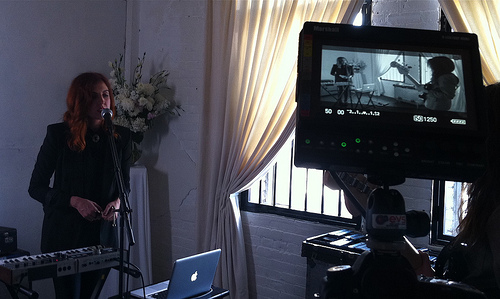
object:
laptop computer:
[131, 247, 221, 297]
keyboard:
[3, 244, 127, 279]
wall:
[130, 0, 233, 264]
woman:
[417, 58, 470, 110]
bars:
[258, 145, 282, 214]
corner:
[117, 25, 203, 174]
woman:
[24, 69, 158, 267]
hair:
[59, 92, 92, 154]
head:
[58, 67, 122, 136]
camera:
[290, 19, 492, 183]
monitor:
[287, 16, 491, 188]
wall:
[237, 204, 359, 296]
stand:
[88, 162, 133, 216]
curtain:
[194, 2, 499, 290]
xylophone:
[333, 205, 424, 287]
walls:
[2, 14, 49, 86]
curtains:
[454, 0, 496, 72]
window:
[238, 0, 498, 243]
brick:
[132, 3, 203, 262]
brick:
[256, 221, 299, 251]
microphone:
[96, 107, 117, 136]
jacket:
[28, 118, 129, 268]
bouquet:
[105, 53, 182, 166]